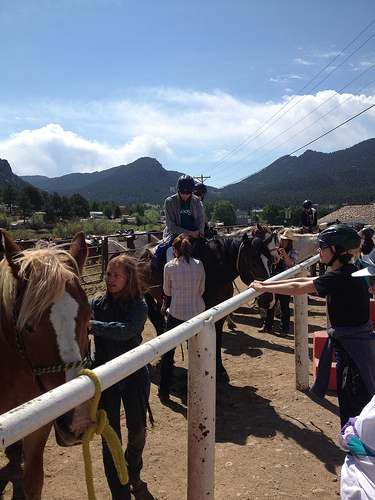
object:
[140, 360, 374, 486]
shade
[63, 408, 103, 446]
nose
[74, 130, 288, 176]
cloud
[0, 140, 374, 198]
bluffs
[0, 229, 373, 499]
ground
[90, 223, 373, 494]
crowd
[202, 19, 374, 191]
wire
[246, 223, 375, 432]
person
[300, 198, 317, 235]
person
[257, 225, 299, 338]
person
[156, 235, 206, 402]
person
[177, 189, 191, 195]
glasses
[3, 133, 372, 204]
hills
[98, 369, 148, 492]
pants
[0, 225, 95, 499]
horse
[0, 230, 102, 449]
head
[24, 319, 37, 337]
eye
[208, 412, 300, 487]
floor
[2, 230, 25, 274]
ear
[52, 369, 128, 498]
rope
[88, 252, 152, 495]
girl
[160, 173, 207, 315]
person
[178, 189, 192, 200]
face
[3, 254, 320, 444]
pole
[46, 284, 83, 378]
marking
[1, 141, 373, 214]
background